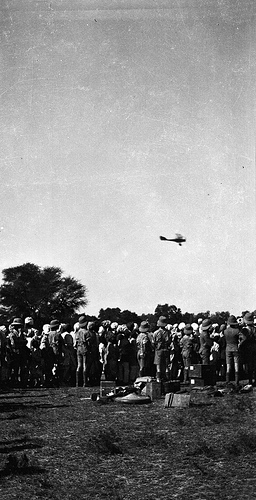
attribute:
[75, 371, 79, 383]
socks — knee-high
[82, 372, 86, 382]
socks — knee-high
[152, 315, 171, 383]
person — wearing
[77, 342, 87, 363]
shorts — dark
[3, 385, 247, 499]
grass — brown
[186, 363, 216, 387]
boxes — square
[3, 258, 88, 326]
tree — large, leafy, above, showing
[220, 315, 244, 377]
person — standing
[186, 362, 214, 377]
box — black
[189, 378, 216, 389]
box — black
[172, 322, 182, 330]
hat — white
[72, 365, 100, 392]
socks — knee-high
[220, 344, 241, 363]
pants — worn, short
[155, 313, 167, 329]
hat — dark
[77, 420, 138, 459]
grass — tall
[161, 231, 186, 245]
airplane — small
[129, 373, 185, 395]
boxes — black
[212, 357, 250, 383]
socks — tall